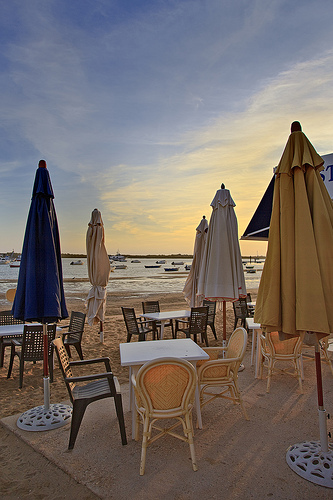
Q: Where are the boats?
A: Water.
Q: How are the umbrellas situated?
A: Closed next to tables.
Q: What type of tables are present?
A: Square.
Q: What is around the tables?
A: Chairs.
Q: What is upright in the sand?
A: Closed umbrellas.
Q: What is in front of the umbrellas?
A: Tables and chairs.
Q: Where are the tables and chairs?
A: Sand.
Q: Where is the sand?
A: Beach.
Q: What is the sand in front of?
A: Water.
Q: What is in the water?
A: Boats.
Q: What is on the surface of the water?
A: White froth.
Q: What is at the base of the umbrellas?
A: Round metal base.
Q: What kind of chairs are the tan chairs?
A: Wicker.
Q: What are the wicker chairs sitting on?
A: Rug.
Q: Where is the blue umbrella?
A: Left of scene.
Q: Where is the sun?
A: To the right.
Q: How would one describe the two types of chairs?
A: Brown and square versus white and rounded.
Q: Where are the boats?
A: On the water.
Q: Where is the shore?
A: Beyond the umbrellas, tables and chairs.